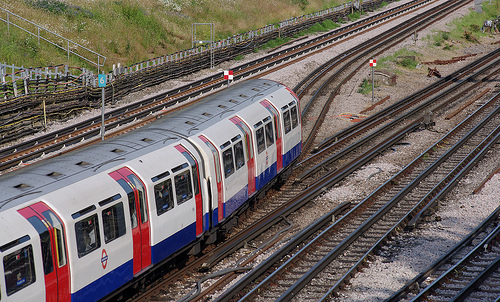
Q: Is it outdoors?
A: Yes, it is outdoors.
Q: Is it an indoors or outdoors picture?
A: It is outdoors.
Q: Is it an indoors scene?
A: No, it is outdoors.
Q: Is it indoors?
A: No, it is outdoors.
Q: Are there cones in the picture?
A: No, there are no cones.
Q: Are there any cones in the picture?
A: No, there are no cones.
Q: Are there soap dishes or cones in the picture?
A: No, there are no cones or soap dishes.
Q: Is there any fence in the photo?
A: Yes, there is a fence.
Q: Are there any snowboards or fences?
A: Yes, there is a fence.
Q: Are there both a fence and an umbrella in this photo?
A: No, there is a fence but no umbrellas.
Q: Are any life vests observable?
A: No, there are no life vests.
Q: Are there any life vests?
A: No, there are no life vests.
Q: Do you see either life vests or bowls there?
A: No, there are no life vests or bowls.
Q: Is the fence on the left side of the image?
A: Yes, the fence is on the left of the image.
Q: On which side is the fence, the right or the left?
A: The fence is on the left of the image.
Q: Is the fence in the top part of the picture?
A: Yes, the fence is in the top of the image.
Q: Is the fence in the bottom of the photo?
A: No, the fence is in the top of the image.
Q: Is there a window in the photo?
A: Yes, there are windows.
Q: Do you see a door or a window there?
A: Yes, there are windows.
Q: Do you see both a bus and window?
A: No, there are windows but no buses.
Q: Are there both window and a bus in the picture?
A: No, there are windows but no buses.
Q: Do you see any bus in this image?
A: No, there are no buses.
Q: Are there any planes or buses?
A: No, there are no buses or planes.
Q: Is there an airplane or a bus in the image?
A: No, there are no buses or airplanes.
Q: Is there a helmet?
A: No, there are no helmets.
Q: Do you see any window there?
A: Yes, there are windows.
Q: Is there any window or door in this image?
A: Yes, there are windows.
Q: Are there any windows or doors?
A: Yes, there are windows.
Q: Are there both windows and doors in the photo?
A: Yes, there are both windows and a door.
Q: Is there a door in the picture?
A: Yes, there is a door.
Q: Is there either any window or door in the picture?
A: Yes, there is a door.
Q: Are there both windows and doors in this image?
A: Yes, there are both a door and windows.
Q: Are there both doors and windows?
A: Yes, there are both a door and windows.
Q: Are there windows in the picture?
A: Yes, there is a window.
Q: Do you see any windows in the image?
A: Yes, there is a window.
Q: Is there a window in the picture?
A: Yes, there is a window.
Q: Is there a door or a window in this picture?
A: Yes, there is a window.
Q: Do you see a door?
A: Yes, there are doors.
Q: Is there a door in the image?
A: Yes, there are doors.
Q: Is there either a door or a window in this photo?
A: Yes, there are doors.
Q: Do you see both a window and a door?
A: Yes, there are both a door and a window.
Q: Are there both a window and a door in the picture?
A: Yes, there are both a door and a window.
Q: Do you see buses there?
A: No, there are no buses.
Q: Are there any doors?
A: Yes, there is a door.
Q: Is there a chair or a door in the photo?
A: Yes, there is a door.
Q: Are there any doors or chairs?
A: Yes, there is a door.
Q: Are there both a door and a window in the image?
A: Yes, there are both a door and a window.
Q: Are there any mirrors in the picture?
A: No, there are no mirrors.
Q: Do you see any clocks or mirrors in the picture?
A: No, there are no mirrors or clocks.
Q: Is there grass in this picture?
A: Yes, there is grass.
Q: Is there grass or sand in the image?
A: Yes, there is grass.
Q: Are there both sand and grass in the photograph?
A: No, there is grass but no sand.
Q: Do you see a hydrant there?
A: No, there are no fire hydrants.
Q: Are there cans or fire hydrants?
A: No, there are no fire hydrants or cans.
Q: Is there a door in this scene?
A: Yes, there are doors.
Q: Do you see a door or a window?
A: Yes, there are doors.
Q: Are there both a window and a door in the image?
A: Yes, there are both a door and a window.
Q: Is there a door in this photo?
A: Yes, there is a door.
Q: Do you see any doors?
A: Yes, there is a door.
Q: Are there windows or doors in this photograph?
A: Yes, there is a door.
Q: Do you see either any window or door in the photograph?
A: Yes, there is a door.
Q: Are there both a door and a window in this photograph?
A: Yes, there are both a door and a window.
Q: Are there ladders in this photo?
A: No, there are no ladders.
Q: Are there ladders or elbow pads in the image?
A: No, there are no ladders or elbow pads.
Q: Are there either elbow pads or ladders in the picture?
A: No, there are no ladders or elbow pads.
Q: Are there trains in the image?
A: Yes, there is a train.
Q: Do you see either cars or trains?
A: Yes, there is a train.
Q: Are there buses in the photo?
A: No, there are no buses.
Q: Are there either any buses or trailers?
A: No, there are no buses or trailers.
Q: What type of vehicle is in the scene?
A: The vehicle is a train.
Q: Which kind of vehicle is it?
A: The vehicle is a train.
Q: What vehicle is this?
A: This is a train.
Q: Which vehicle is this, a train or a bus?
A: This is a train.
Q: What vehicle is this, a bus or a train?
A: This is a train.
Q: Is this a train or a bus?
A: This is a train.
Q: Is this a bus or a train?
A: This is a train.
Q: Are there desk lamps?
A: No, there are no desk lamps.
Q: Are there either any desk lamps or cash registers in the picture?
A: No, there are no desk lamps or cash registers.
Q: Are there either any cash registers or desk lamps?
A: No, there are no desk lamps or cash registers.